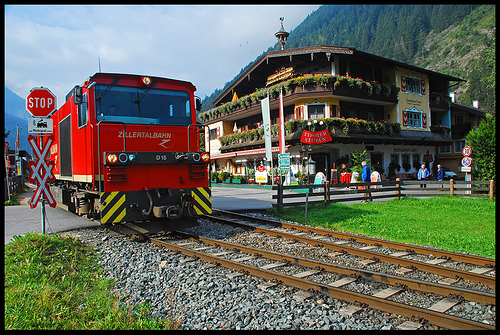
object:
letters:
[28, 96, 36, 109]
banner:
[297, 128, 333, 145]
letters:
[116, 131, 125, 139]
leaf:
[372, 13, 395, 40]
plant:
[348, 148, 375, 184]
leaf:
[393, 23, 418, 35]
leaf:
[321, 12, 344, 24]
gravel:
[314, 298, 327, 305]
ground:
[0, 184, 499, 334]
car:
[40, 72, 211, 192]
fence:
[270, 176, 495, 213]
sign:
[24, 85, 59, 119]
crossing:
[24, 159, 58, 211]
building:
[194, 12, 487, 190]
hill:
[197, 3, 498, 117]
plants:
[431, 124, 453, 141]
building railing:
[194, 73, 391, 124]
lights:
[118, 152, 129, 165]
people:
[416, 163, 431, 190]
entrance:
[306, 151, 333, 181]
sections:
[4, 86, 33, 160]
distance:
[1, 6, 219, 143]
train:
[36, 71, 213, 226]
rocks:
[242, 315, 254, 325]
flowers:
[318, 120, 324, 126]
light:
[104, 151, 120, 165]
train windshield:
[92, 83, 193, 127]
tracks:
[131, 227, 500, 334]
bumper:
[96, 185, 214, 226]